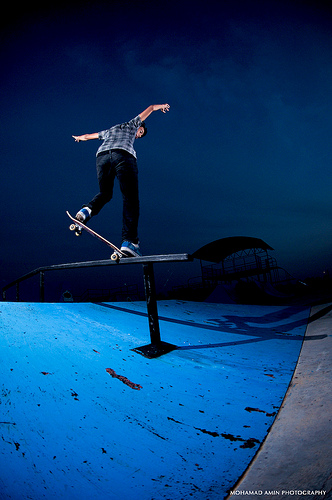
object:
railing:
[0, 253, 195, 360]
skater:
[66, 104, 170, 261]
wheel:
[69, 223, 75, 230]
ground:
[238, 113, 259, 144]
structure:
[191, 236, 289, 298]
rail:
[0, 253, 190, 360]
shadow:
[206, 304, 327, 341]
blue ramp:
[0, 297, 312, 500]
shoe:
[74, 207, 89, 231]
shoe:
[120, 240, 142, 257]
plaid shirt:
[95, 116, 142, 160]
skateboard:
[65, 210, 128, 261]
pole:
[143, 262, 161, 346]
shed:
[191, 235, 291, 303]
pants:
[81, 148, 140, 244]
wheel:
[111, 253, 119, 261]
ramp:
[1, 296, 305, 496]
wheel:
[110, 252, 121, 261]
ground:
[12, 301, 282, 498]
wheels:
[69, 223, 82, 236]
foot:
[74, 206, 92, 234]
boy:
[72, 103, 170, 257]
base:
[129, 341, 181, 359]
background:
[279, 241, 300, 263]